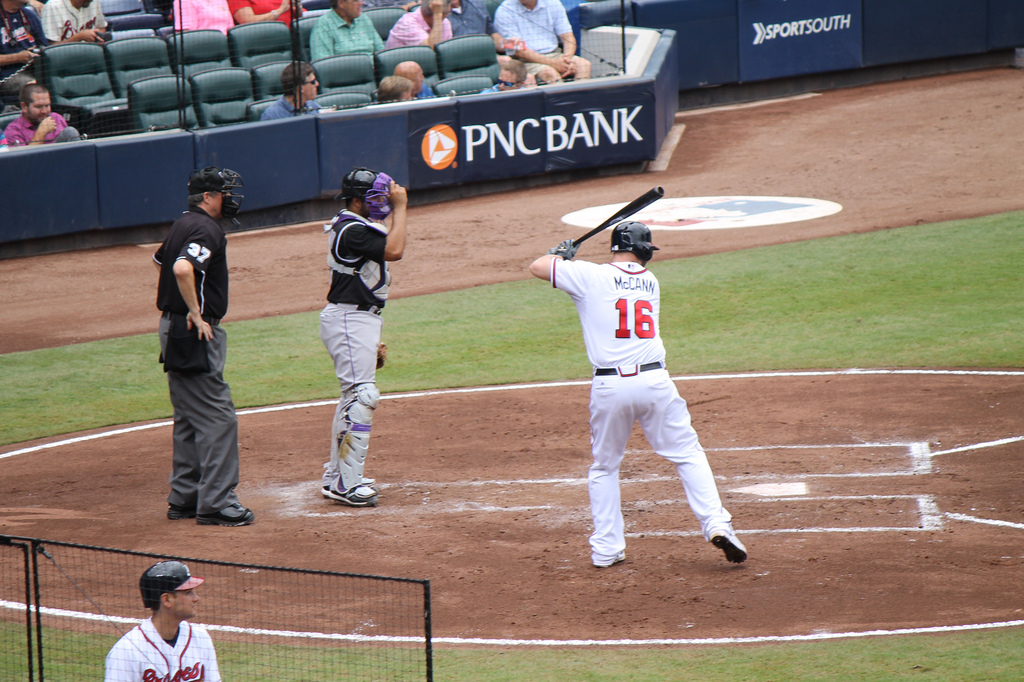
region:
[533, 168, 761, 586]
a baseball player ready to swing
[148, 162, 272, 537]
an umpire with his hands on waist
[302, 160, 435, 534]
a baseball catcher standing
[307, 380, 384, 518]
leg protection for an athlete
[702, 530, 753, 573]
black sole on baseball shoes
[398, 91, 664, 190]
bank advertisement on a wall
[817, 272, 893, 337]
a patch of artificial grass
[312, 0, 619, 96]
crowd behind a steel fence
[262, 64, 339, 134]
man with sunglasses and blue shirt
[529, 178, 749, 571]
Batter standing at the plate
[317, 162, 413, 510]
Catcher with his hand on his mask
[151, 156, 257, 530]
Umpire standing behind the catcher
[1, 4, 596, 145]
People sitting in the stadium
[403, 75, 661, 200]
PNC Bank advertisement on the wall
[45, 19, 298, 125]
Empty seats in the stands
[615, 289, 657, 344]
The number 16 on a player's jersey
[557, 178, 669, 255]
Bat in the player's hands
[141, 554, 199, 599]
Helmet on the baseball player's head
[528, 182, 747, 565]
Baseball player holding the bat up.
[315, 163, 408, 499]
Catcher standing with hand on face mask.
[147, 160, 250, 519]
Umpire in black standing with hand on hip.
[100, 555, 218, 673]
Baseball player in foreground looking right.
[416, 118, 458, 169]
Round orange and white logo.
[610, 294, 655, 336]
Red number on back of the batter's uniform.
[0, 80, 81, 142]
Man in purple shirt sitting in front row.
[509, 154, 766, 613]
baseball player swing black bat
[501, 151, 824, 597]
baseball player standing at home plate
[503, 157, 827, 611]
Baseball player warming up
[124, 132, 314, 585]
MLB Umpire standing at home plate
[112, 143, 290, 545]
MLB Umpire standing behind home plate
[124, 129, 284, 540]
MLB Umpire wearing full face mask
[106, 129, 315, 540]
Umpire standing behind catcher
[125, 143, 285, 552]
MLB Umpire wearing number "37"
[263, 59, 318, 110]
person at the baseball game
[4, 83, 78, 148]
person at the baseball game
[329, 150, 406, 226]
Catcher wearing purple face mask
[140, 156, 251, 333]
Umpire has on a black shirt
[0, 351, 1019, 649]
White lines on the dirt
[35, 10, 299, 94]
Four empty green seats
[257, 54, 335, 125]
A person has on a blue shirt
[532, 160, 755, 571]
A baseball player holding a bat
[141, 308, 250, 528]
A pair of gray pants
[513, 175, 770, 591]
A baseball player.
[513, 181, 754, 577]
A man holding a baseball bat up in the air.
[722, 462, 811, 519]
A white home plate.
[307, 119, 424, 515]
A baseball catcher.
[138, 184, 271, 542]
The umpire.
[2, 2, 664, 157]
Spectators watching the game.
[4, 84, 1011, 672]
A grass and dirt field.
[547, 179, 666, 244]
A black baseball bat.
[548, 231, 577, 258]
Batting gloves.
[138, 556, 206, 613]
A black and red baseball helmet.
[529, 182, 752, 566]
man standing with a bat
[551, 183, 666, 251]
long thin black bat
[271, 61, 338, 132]
A person is sitting down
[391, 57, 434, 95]
A person is sitting down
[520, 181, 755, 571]
man swinging a bat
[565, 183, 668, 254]
bat in mans hands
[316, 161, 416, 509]
man adjusting face mask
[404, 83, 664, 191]
advertisement on wall